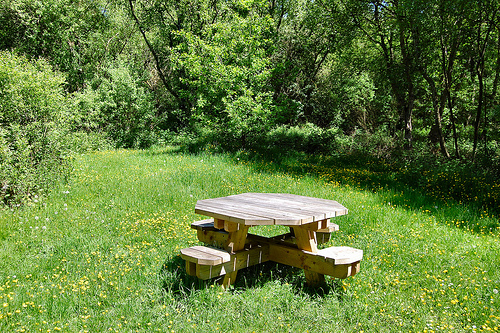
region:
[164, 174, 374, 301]
Table with chairs on a field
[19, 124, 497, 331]
Table is on a green grass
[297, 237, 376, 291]
Sit is attached to the table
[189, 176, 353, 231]
Table is made of wood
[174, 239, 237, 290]
Sit is made of wood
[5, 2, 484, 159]
Trees surround an open field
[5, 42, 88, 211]
Bush on the field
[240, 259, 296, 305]
Shadow of the table over the grass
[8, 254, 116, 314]
Yellow flowers on a field of green grass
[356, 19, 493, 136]
Branches of trees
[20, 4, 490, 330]
The grass is green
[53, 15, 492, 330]
The photo was taken during the daytime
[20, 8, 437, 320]
There is a bench in the photo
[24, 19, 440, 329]
No one is in the photo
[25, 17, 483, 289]
There are trees in the background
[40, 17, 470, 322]
It is a sunny day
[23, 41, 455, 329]
There are yellow flowers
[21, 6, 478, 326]
There is one bench in the photo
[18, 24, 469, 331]
There are fours seats connected to the table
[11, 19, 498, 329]
There are no animals in the photo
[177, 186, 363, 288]
wooden picnic table in tall grass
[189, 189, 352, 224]
top of picnic table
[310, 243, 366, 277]
seat on left of picture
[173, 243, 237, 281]
seat on right of picture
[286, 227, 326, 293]
table leg on right of picture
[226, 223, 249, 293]
table leg on left of picture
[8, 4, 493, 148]
brush and trees behind table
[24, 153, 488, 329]
green grass surrounding table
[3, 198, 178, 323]
yellow wild flowers in left of picture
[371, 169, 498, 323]
yellow wild flowers on right of picture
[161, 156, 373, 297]
Wooden park table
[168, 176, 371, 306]
Picnic table in the middle of a meadow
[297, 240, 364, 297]
Sit of wooden park table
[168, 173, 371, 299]
Picnic table is wooden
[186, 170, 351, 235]
Picnic table has octagon shape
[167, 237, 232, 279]
Sit of picnic table has octagon shape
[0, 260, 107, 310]
Yellow flowers in the meadow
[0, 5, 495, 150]
Trees in the forest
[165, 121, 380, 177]
Shadow of trees cast on the green grass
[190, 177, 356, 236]
Pick nick table has wood boards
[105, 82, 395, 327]
There is one picnic table in the picture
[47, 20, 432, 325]
The picnic table has four seats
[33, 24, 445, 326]
There is grass in the photo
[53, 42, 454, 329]
There is no one in the photo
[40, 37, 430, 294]
The photo was taken in the daytime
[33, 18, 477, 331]
The photo was taken on a sunny day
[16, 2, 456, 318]
There are yellow flowers in the grass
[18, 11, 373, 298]
There are no birds in the picture